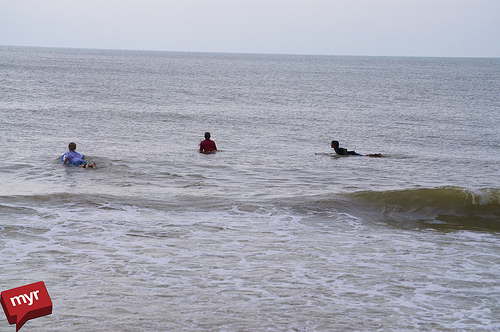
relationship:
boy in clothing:
[199, 132, 218, 154] [334, 148, 358, 156]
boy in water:
[199, 132, 218, 154] [2, 44, 498, 325]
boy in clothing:
[199, 132, 218, 154] [200, 136, 219, 152]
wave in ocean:
[282, 183, 498, 251] [2, 35, 498, 320]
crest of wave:
[447, 182, 499, 204] [307, 187, 499, 222]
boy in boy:
[328, 138, 385, 158] [55, 139, 96, 171]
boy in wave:
[61, 142, 97, 170] [282, 183, 498, 208]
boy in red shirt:
[199, 132, 218, 154] [199, 138, 216, 151]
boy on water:
[174, 119, 226, 163] [2, 44, 498, 325]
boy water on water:
[43, 134, 110, 181] [2, 44, 498, 325]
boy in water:
[61, 142, 97, 170] [158, 214, 433, 301]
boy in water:
[199, 132, 218, 154] [158, 214, 433, 301]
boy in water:
[331, 140, 383, 157] [158, 214, 433, 301]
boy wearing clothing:
[331, 140, 383, 157] [334, 148, 374, 158]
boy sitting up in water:
[199, 132, 218, 154] [2, 44, 498, 325]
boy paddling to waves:
[199, 132, 218, 154] [44, 96, 398, 128]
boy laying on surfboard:
[331, 140, 383, 157] [309, 150, 392, 160]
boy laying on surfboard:
[199, 132, 218, 154] [187, 146, 226, 151]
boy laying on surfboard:
[61, 142, 97, 170] [57, 155, 97, 172]